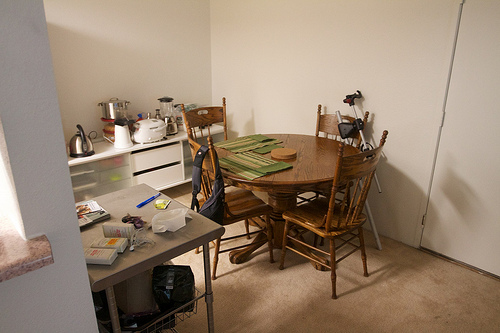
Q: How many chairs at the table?
A: 4.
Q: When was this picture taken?
A: Daytime.